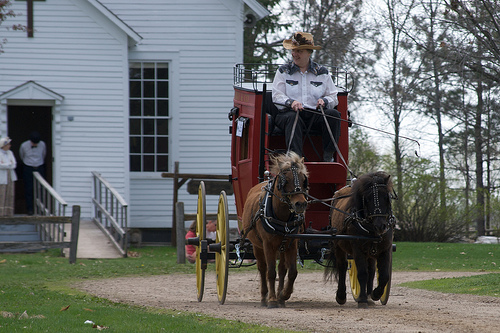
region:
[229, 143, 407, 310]
Two horses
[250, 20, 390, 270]
The driver guiding the horses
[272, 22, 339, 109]
The person is wearing a hat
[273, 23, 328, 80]
The person is smiling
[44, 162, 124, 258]
A small ramp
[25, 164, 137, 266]
The ramp has wooden railings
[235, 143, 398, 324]
The horses are walking on dirt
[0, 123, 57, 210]
Two people by the building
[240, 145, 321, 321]
horse drawing a carriage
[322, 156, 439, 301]
horse drawing a carriage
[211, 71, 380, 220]
red wagon on path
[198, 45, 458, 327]
horses drawing a red wagon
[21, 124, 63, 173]
man at the door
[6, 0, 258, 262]
white building in back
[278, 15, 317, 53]
man wearing a hat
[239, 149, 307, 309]
BROWN HORSE PULLING COACH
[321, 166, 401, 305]
BROWN HORSE PULLING COACH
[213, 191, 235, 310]
WHEEL OF STAGE COACH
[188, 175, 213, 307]
WHEEL OF STAGE COACH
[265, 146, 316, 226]
HEAD OF BROWN HORSE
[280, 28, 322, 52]
COWBOY HAT ON MAN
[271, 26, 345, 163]
STAGECOACH DRIVER WEARING HAT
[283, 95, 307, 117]
HAND OF STAGECOACH DRIVER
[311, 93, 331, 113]
HAND OF STAGECOACH DRIVER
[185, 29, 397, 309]
A horse drawn carriage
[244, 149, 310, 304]
A light brown horse attached to a cart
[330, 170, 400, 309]
A dark brown horse attached to a cart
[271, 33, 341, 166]
A man driving a carriage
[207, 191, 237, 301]
A wooden wheel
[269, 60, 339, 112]
A white long sleeved shirt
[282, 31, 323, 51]
A tan cowboy har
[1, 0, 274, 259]
A white church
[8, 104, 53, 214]
An open door way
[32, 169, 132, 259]
A wooden ramp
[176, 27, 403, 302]
horses pulling a stage couch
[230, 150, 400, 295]
a team of brown horses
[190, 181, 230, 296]
yellow wooden wheels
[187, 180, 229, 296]
yellow wagon wheels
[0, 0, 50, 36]
part of a brown cross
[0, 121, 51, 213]
people standing in a door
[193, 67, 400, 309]
horses pulling a red stage couch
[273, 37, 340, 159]
a man on a stage couch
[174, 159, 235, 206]
a wooden sign on post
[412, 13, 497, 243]
tall trees in th edistance